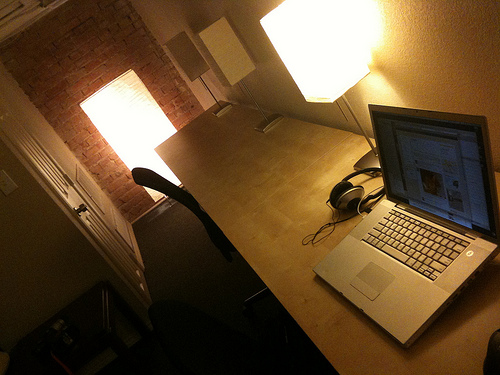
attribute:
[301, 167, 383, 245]
headphones — large, over the ear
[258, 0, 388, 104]
light — bright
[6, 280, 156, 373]
end table — short , wooden 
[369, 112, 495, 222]
screen — blue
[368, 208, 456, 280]
keyboards — silver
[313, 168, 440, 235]
headphones — over-the-head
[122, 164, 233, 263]
chair — black, rolling, office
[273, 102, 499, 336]
laptop — open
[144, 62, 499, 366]
table — long, tan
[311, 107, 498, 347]
silver laptop — open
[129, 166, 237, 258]
chair — black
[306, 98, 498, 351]
laptop — open, silver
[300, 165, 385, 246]
headphone — curved, looped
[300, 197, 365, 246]
wire — thin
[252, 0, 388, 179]
lamp — lit up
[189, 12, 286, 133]
light — second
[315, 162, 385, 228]
headphones — Black 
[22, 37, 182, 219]
brick — light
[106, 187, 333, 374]
flooring — smooth, black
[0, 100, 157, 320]
door — paneled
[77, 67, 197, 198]
doorway — lit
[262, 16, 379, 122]
lamps — three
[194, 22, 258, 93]
lamps — three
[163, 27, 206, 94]
lamps — three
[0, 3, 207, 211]
wall — brick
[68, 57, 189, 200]
panel — bright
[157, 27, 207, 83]
shade — rectangular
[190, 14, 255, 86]
shade — rectangular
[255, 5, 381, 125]
shade — rectangular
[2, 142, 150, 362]
wall — white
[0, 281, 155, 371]
area — dark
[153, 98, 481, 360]
table — long, wooden